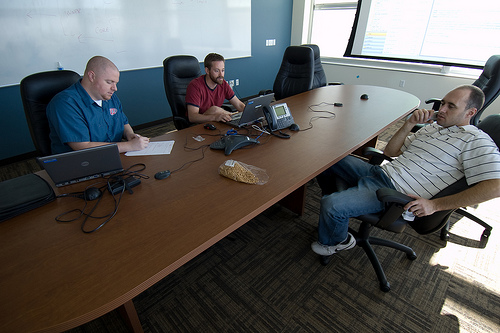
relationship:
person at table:
[46, 56, 150, 157] [0, 84, 421, 333]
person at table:
[186, 53, 245, 123] [0, 84, 421, 333]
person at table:
[310, 85, 499, 256] [0, 84, 421, 333]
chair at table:
[273, 46, 313, 101] [0, 84, 421, 333]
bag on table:
[218, 159, 269, 186] [0, 84, 421, 333]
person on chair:
[46, 56, 150, 157] [21, 70, 82, 157]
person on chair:
[186, 53, 245, 123] [163, 55, 200, 131]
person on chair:
[310, 85, 499, 256] [320, 115, 500, 292]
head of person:
[204, 53, 225, 85] [186, 53, 245, 123]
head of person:
[84, 56, 120, 101] [46, 56, 150, 157]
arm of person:
[51, 99, 150, 160] [46, 56, 150, 157]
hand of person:
[403, 193, 433, 218] [310, 85, 499, 256]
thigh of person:
[335, 182, 392, 216] [310, 85, 499, 256]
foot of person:
[311, 232, 357, 256] [310, 85, 499, 256]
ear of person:
[88, 69, 95, 84] [46, 56, 150, 157]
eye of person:
[449, 104, 454, 109] [310, 85, 499, 256]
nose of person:
[111, 82, 117, 91] [46, 56, 150, 157]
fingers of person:
[403, 193, 424, 218] [310, 85, 499, 256]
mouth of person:
[438, 113, 448, 120] [310, 85, 499, 256]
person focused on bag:
[310, 85, 499, 256] [218, 159, 269, 186]